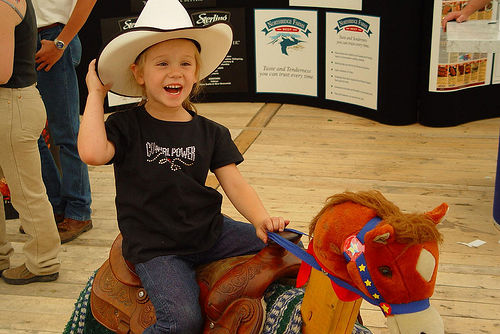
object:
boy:
[75, 1, 293, 333]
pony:
[59, 190, 447, 334]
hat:
[94, 0, 235, 100]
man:
[21, 0, 100, 248]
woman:
[0, 1, 60, 287]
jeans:
[128, 214, 274, 334]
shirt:
[101, 100, 247, 265]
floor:
[282, 124, 472, 189]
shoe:
[56, 215, 93, 246]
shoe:
[18, 218, 64, 234]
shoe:
[1, 261, 62, 285]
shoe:
[0, 250, 13, 274]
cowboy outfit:
[94, 0, 274, 332]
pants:
[0, 82, 64, 276]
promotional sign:
[325, 8, 381, 112]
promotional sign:
[252, 7, 317, 94]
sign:
[428, 2, 499, 94]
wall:
[239, 0, 498, 126]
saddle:
[85, 223, 302, 333]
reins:
[269, 235, 315, 266]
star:
[359, 263, 367, 271]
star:
[364, 279, 372, 287]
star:
[371, 293, 380, 299]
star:
[380, 304, 389, 314]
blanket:
[64, 268, 309, 334]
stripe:
[238, 102, 284, 153]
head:
[326, 188, 453, 333]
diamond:
[416, 248, 436, 281]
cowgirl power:
[143, 142, 197, 162]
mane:
[306, 188, 426, 234]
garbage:
[456, 238, 484, 247]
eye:
[378, 264, 392, 278]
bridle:
[341, 204, 446, 315]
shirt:
[1, 1, 40, 92]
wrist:
[54, 33, 72, 53]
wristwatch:
[54, 38, 65, 50]